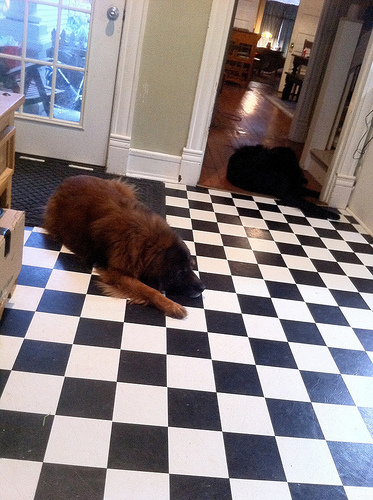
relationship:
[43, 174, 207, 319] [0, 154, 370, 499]
dog lying on floor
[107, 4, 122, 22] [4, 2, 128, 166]
knob on door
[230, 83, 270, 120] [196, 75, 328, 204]
reflection on floor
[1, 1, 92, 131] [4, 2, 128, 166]
panes on door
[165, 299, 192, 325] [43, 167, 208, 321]
paw of dog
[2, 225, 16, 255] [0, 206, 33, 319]
tape on box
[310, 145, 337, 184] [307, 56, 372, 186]
step on stairwell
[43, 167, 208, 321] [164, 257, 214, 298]
dog with face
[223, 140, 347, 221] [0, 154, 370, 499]
dog laying on floor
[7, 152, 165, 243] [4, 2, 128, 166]
mat in front of door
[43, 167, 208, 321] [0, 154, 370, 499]
dog on floor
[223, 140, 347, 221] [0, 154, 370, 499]
dog on floor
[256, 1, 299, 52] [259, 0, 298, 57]
curtains covering window